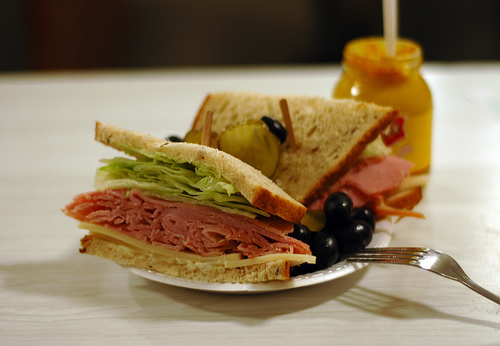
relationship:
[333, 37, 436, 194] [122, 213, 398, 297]
bottle beside dish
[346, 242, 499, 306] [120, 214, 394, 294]
fork on dish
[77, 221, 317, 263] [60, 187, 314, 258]
cheese under meat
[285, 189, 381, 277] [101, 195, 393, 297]
olive pile on plate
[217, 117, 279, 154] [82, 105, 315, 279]
pickle on top of sandwich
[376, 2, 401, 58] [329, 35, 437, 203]
utensil in a bottle of mustard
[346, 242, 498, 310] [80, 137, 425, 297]
fork leaning on side of plate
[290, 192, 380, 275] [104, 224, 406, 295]
olives on edge of plate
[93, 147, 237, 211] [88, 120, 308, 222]
lettuce under bread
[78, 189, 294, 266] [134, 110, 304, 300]
meat in middle of sandwich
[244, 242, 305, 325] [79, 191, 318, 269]
cheese under meat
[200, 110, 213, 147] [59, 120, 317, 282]
toothpick holding together sandwich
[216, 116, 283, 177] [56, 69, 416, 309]
pickle on top of sandwich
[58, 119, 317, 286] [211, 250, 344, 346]
sandwich sitting on a plate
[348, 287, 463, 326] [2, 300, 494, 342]
shadow of a fork on table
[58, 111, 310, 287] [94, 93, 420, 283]
sandwich on wheat bread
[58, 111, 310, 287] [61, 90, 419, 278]
sandwich on wheat bread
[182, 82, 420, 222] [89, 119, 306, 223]
sandwich on bread